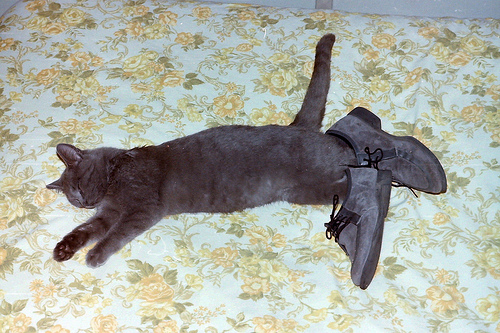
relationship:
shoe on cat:
[325, 171, 385, 287] [40, 32, 451, 287]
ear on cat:
[51, 137, 83, 164] [40, 28, 358, 265]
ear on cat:
[42, 175, 63, 191] [40, 28, 358, 265]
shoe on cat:
[324, 106, 448, 198] [65, 114, 293, 255]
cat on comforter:
[44, 32, 357, 269] [15, 28, 445, 316]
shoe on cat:
[322, 168, 393, 290] [24, 120, 292, 261]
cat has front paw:
[40, 28, 358, 265] [51, 240, 77, 263]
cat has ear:
[44, 32, 357, 269] [50, 136, 90, 168]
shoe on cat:
[327, 111, 452, 201] [40, 28, 358, 265]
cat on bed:
[40, 28, 358, 265] [1, 0, 495, 330]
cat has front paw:
[44, 32, 357, 269] [49, 232, 130, 266]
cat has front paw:
[40, 28, 358, 265] [47, 240, 75, 263]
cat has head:
[40, 28, 358, 265] [37, 134, 113, 204]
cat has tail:
[44, 32, 357, 269] [294, 35, 344, 133]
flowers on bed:
[121, 251, 185, 311] [1, 0, 495, 330]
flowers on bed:
[232, 256, 272, 303] [1, 0, 495, 330]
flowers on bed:
[400, 261, 485, 330] [1, 0, 495, 330]